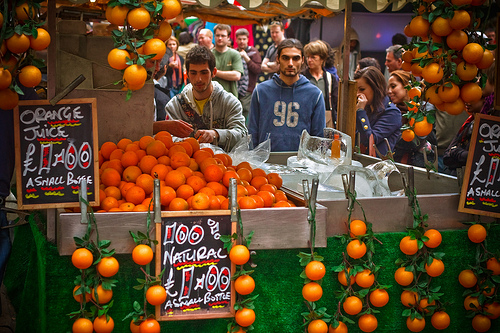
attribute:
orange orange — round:
[173, 160, 207, 210]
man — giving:
[175, 54, 256, 131]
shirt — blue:
[252, 74, 327, 149]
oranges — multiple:
[145, 140, 216, 192]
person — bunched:
[166, 51, 252, 146]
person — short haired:
[247, 37, 326, 149]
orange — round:
[206, 163, 221, 180]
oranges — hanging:
[73, 221, 498, 329]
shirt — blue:
[244, 39, 326, 151]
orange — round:
[345, 216, 367, 240]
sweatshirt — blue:
[248, 71, 325, 151]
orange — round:
[166, 152, 186, 169]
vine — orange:
[306, 221, 318, 256]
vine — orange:
[341, 202, 354, 227]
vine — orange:
[408, 194, 425, 223]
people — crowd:
[356, 66, 403, 161]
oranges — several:
[191, 193, 210, 210]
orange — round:
[159, 173, 213, 200]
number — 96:
[270, 100, 300, 126]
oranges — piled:
[109, 129, 265, 220]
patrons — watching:
[164, 20, 286, 64]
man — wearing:
[247, 40, 324, 153]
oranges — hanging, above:
[395, 2, 498, 169]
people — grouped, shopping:
[172, 25, 432, 155]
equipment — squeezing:
[268, 129, 402, 201]